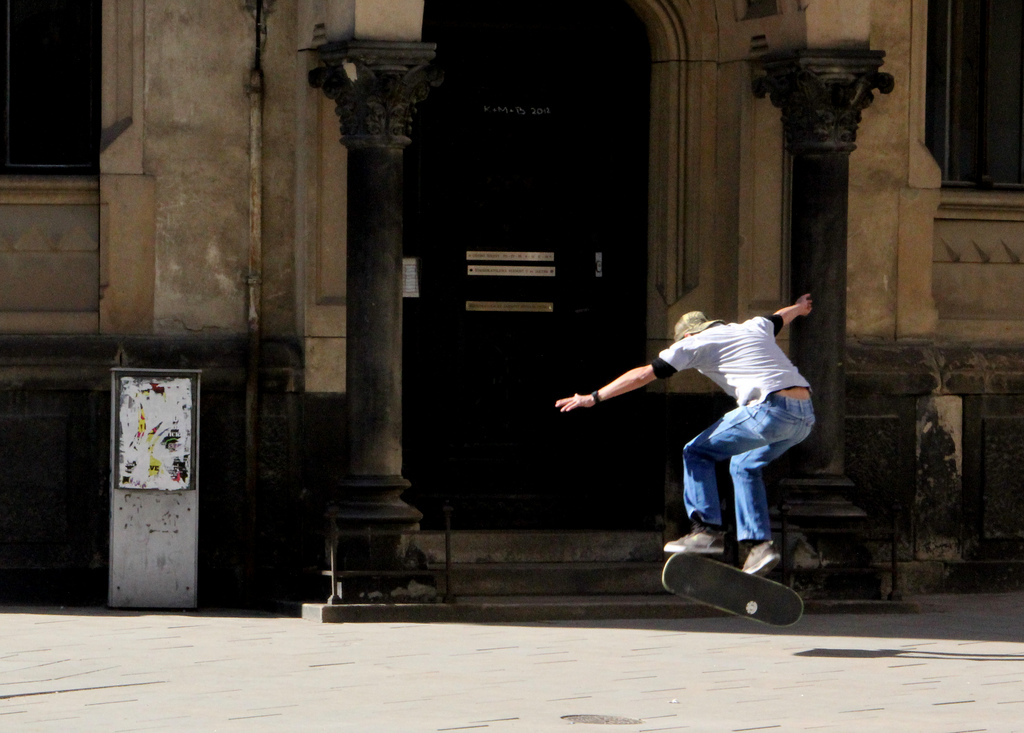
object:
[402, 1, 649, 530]
door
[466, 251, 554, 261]
name plate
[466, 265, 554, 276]
name plate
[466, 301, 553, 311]
name plate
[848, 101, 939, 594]
stone